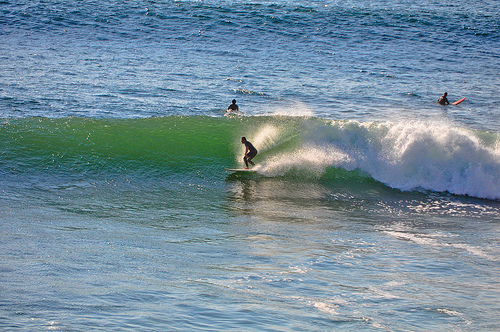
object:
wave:
[0, 113, 500, 200]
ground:
[0, 0, 500, 332]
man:
[437, 92, 450, 106]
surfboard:
[448, 96, 465, 106]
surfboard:
[225, 168, 260, 172]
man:
[227, 99, 238, 112]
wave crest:
[318, 118, 500, 201]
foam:
[195, 102, 500, 332]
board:
[453, 97, 466, 105]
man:
[241, 136, 258, 169]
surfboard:
[448, 92, 469, 109]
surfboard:
[224, 109, 244, 117]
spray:
[234, 120, 359, 182]